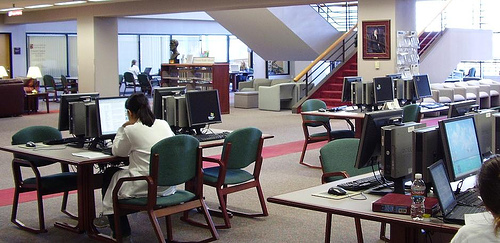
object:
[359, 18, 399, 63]
picture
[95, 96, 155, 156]
computer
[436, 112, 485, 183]
computer monitor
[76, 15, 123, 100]
pole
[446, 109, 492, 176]
screen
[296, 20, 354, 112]
stair railing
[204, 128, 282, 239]
chair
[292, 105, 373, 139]
desk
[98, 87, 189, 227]
woman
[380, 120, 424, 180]
monitor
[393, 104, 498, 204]
hot computer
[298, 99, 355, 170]
chair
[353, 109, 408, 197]
computer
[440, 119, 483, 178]
monitor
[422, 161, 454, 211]
monitor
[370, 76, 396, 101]
monitor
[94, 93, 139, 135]
monitor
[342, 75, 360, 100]
monitor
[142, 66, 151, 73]
monitor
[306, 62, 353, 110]
staircase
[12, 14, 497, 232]
computer lap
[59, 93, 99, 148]
computer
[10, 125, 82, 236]
chair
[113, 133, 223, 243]
chair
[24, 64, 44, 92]
lamp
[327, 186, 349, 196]
computer mouse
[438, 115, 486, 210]
computer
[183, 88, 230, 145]
computer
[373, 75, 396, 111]
computer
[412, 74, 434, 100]
computer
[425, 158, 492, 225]
computer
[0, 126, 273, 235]
computer desk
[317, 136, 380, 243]
chair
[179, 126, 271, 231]
chair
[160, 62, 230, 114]
bookshelf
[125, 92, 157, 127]
hair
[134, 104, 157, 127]
ponytail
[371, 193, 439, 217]
book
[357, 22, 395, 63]
photo wall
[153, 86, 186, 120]
computer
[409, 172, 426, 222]
bottle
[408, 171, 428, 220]
water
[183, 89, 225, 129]
monitor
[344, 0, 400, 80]
wall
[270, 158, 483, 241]
desk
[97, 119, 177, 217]
coat